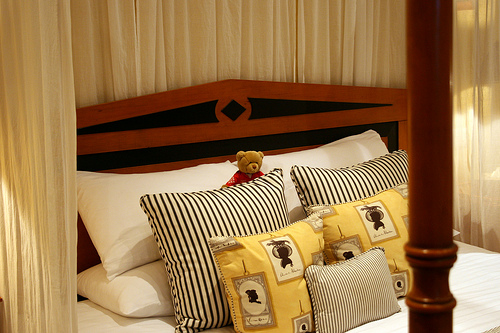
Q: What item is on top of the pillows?
A: A teddy bear.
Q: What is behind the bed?
A: Curtains.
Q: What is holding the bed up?
A: Posts.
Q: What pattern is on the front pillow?
A: Vertical stripes.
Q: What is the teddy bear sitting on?
A: A pillow.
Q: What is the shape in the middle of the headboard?
A: A diamond.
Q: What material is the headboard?
A: Wood.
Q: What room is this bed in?
A: A bedroom.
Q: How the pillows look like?
A: Decorative.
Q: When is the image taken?
A: Pillows are on bed.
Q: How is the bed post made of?
A: Wood.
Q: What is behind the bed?
A: Curtains.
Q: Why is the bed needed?
A: Sleep.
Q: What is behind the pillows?
A: Teddy bear.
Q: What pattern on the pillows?
A: Striped.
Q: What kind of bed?
A: Canopy.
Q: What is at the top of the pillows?
A: Teddy bear.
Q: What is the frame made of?
A: Wood.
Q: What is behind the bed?
A: Curtain.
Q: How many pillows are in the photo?
A: Nine.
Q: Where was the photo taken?
A: Bedroom.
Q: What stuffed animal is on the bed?
A: Bear.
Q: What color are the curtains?
A: Ivory.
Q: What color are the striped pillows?
A: Navy.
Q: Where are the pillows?
A: Bed.